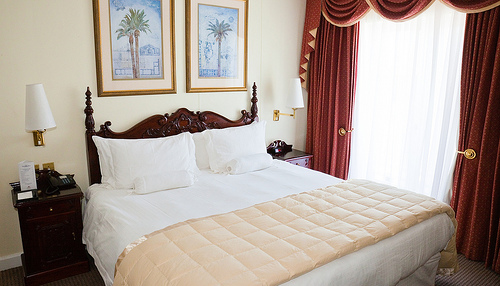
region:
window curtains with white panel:
[297, 2, 499, 271]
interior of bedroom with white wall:
[0, 3, 497, 282]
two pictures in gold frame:
[93, 0, 249, 98]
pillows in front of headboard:
[84, 82, 264, 184]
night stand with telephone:
[11, 171, 98, 284]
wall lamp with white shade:
[22, 79, 57, 146]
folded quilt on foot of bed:
[84, 176, 459, 283]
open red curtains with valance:
[296, 2, 496, 267]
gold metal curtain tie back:
[454, 148, 476, 160]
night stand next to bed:
[266, 140, 314, 167]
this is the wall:
[21, 27, 81, 71]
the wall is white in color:
[9, 21, 60, 53]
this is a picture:
[108, 10, 185, 78]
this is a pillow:
[113, 127, 193, 168]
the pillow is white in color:
[130, 143, 155, 154]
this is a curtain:
[301, 12, 339, 127]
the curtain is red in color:
[321, 48, 333, 85]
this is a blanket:
[208, 202, 305, 274]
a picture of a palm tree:
[81, 0, 179, 170]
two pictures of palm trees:
[91, 0, 253, 99]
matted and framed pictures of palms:
[91, 1, 253, 98]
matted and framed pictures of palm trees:
[88, 0, 253, 100]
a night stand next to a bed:
[5, 60, 265, 284]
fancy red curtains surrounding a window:
[295, 5, 497, 284]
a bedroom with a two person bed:
[6, 4, 496, 279]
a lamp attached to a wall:
[14, 78, 67, 150]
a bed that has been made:
[73, 80, 471, 285]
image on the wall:
[181, 5, 255, 94]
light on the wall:
[16, 69, 62, 145]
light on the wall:
[266, 64, 303, 126]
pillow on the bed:
[93, 129, 205, 191]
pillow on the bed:
[203, 125, 275, 172]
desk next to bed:
[1, 169, 98, 270]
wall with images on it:
[6, 5, 320, 185]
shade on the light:
[26, 86, 49, 124]